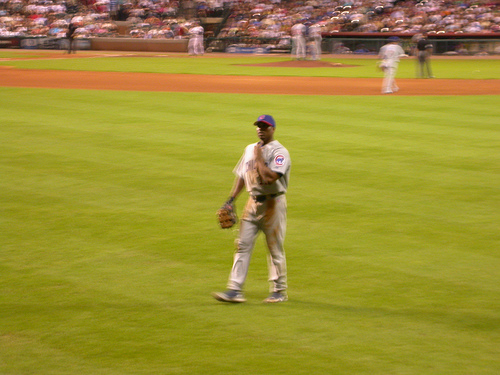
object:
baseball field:
[0, 41, 498, 373]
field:
[1, 47, 497, 374]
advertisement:
[227, 43, 271, 55]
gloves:
[216, 203, 237, 229]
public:
[330, 0, 495, 36]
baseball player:
[290, 18, 308, 61]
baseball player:
[308, 21, 326, 60]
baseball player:
[186, 19, 205, 57]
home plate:
[101, 42, 123, 54]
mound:
[238, 41, 330, 82]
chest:
[242, 146, 282, 172]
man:
[66, 22, 77, 54]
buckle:
[246, 190, 284, 219]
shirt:
[233, 139, 288, 204]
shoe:
[263, 290, 288, 304]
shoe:
[213, 288, 247, 303]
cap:
[254, 113, 276, 127]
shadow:
[302, 290, 497, 342]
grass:
[35, 44, 495, 372]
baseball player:
[212, 114, 291, 303]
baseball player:
[377, 40, 407, 94]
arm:
[254, 152, 285, 186]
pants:
[225, 194, 289, 294]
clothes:
[417, 39, 433, 51]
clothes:
[68, 23, 77, 39]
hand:
[215, 201, 237, 230]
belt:
[250, 191, 287, 201]